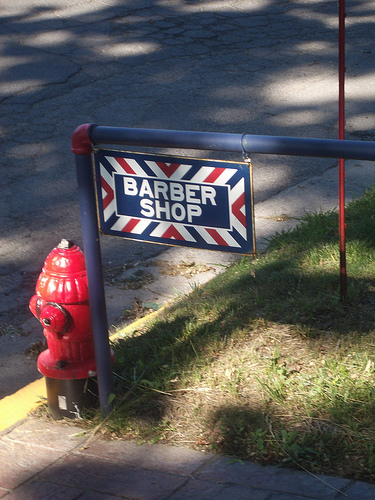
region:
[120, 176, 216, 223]
The words BARBER SHOP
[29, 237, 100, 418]
A red and black fire hydrant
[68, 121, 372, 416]
Navy blue and red pole with a sign hanging off it.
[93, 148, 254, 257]
A barber shop sign hanging.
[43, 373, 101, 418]
Bottom black base of a fire hydrant.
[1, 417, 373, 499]
Gray brick concrete walkway.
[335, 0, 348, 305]
A thin red pole to the right of the barber shop sign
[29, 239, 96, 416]
Red fire hydrant in the grass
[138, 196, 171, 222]
White SH letters in shop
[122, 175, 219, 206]
The word BARBER.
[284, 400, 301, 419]
part of the grass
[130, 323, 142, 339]
edge of a pavement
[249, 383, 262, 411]
part of a lawn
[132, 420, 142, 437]
edge of a lawn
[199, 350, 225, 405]
edge of a lawn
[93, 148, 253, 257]
A sign indicating the presence of a Barber Shop.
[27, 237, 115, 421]
A red fire hydrant near the sidewalk.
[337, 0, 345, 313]
A red pole in a sidewalk.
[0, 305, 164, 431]
The yellow line separating the sidewalk from the pavement.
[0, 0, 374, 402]
The road is at the left of the sidewalk.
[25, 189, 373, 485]
A large amount of grass is in the sidewalk.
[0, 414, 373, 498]
A squared piece of concrete on the sidewalk.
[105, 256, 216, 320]
Some trash is laying on the floor.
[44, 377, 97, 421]
The black part of a fire hydrant.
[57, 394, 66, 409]
A used white sticker on a fire hydrant.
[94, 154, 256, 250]
The sign says "barber shop"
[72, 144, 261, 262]
The sign is red, white and blue.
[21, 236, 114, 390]
This is a fire hydrant.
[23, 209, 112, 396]
The hydrant is red.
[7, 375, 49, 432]
The edge of the curb is yellow.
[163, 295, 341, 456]
The grass is partially brown.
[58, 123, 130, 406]
The pipe is red and blue.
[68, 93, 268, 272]
the sign is hanging from railing.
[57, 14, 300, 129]
This is a street.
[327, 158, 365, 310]
This pole is dark red.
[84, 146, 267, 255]
sign is blue white and red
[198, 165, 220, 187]
the line is red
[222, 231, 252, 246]
the line is blue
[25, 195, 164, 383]
fire hydrant is red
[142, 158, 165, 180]
the background is white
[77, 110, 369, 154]
sign pole is blue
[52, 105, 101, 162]
part of pole is red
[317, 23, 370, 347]
the pole is red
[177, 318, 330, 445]
light shining on grass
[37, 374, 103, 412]
bottom of hydrant is black